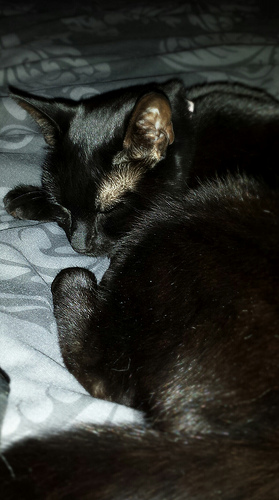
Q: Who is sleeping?
A: The cat.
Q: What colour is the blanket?
A: Grey.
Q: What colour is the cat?
A: Black.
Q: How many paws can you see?
A: 2.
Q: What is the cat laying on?
A: Bed.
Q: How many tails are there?
A: 1.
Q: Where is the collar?
A: Around the cat's neck.